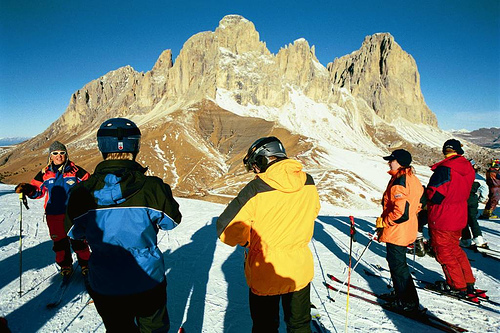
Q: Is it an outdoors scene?
A: Yes, it is outdoors.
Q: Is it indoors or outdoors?
A: It is outdoors.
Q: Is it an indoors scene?
A: No, it is outdoors.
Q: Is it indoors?
A: No, it is outdoors.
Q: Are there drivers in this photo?
A: No, there are no drivers.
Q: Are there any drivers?
A: No, there are no drivers.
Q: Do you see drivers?
A: No, there are no drivers.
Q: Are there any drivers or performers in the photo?
A: No, there are no drivers or performers.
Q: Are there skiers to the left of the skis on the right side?
A: Yes, there is a skier to the left of the skis.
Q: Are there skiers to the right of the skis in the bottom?
A: No, the skier is to the left of the skis.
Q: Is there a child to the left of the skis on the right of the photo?
A: No, there is a skier to the left of the skis.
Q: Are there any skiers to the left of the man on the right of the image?
A: Yes, there is a skier to the left of the man.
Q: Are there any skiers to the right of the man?
A: No, the skier is to the left of the man.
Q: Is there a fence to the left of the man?
A: No, there is a skier to the left of the man.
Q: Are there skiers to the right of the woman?
A: Yes, there is a skier to the right of the woman.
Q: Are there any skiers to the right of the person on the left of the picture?
A: Yes, there is a skier to the right of the woman.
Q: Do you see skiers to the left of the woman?
A: No, the skier is to the right of the woman.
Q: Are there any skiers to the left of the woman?
A: No, the skier is to the right of the woman.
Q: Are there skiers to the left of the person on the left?
A: No, the skier is to the right of the woman.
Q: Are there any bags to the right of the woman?
A: No, there is a skier to the right of the woman.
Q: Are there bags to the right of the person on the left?
A: No, there is a skier to the right of the woman.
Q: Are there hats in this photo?
A: Yes, there is a hat.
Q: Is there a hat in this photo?
A: Yes, there is a hat.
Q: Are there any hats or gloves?
A: Yes, there is a hat.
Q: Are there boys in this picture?
A: No, there are no boys.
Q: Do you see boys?
A: No, there are no boys.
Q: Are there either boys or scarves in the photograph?
A: No, there are no boys or scarves.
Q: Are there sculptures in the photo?
A: No, there are no sculptures.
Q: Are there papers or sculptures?
A: No, there are no sculptures or papers.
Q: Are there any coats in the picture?
A: Yes, there is a coat.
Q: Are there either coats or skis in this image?
A: Yes, there is a coat.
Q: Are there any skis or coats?
A: Yes, there is a coat.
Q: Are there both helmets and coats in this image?
A: Yes, there are both a coat and a helmet.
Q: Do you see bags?
A: No, there are no bags.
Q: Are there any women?
A: Yes, there is a woman.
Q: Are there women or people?
A: Yes, there is a woman.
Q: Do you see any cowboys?
A: No, there are no cowboys.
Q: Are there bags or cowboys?
A: No, there are no cowboys or bags.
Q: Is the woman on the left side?
A: Yes, the woman is on the left of the image.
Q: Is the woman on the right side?
A: No, the woman is on the left of the image.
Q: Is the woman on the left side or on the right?
A: The woman is on the left of the image.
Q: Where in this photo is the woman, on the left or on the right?
A: The woman is on the left of the image.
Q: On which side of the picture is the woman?
A: The woman is on the left of the image.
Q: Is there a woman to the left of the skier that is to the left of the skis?
A: Yes, there is a woman to the left of the skier.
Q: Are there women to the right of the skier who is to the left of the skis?
A: No, the woman is to the left of the skier.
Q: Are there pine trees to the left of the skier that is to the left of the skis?
A: No, there is a woman to the left of the skier.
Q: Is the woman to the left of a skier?
A: Yes, the woman is to the left of a skier.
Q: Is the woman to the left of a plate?
A: No, the woman is to the left of a skier.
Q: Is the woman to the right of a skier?
A: No, the woman is to the left of a skier.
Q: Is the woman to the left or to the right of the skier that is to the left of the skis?
A: The woman is to the left of the skier.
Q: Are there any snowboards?
A: No, there are no snowboards.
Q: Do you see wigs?
A: No, there are no wigs.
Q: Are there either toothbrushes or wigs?
A: No, there are no wigs or toothbrushes.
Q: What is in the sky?
A: The clouds are in the sky.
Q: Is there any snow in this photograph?
A: Yes, there is snow.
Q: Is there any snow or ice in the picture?
A: Yes, there is snow.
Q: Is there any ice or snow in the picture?
A: Yes, there is snow.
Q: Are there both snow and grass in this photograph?
A: No, there is snow but no grass.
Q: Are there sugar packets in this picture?
A: No, there are no sugar packets.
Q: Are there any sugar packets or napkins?
A: No, there are no sugar packets or napkins.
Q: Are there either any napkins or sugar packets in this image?
A: No, there are no sugar packets or napkins.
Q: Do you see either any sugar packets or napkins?
A: No, there are no sugar packets or napkins.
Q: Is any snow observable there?
A: Yes, there is snow.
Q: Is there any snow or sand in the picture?
A: Yes, there is snow.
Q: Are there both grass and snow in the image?
A: No, there is snow but no grass.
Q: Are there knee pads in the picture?
A: No, there are no knee pads.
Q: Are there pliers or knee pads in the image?
A: No, there are no knee pads or pliers.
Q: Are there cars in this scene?
A: No, there are no cars.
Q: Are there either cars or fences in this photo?
A: No, there are no cars or fences.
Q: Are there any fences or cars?
A: No, there are no cars or fences.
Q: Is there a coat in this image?
A: Yes, there is a coat.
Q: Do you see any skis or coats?
A: Yes, there is a coat.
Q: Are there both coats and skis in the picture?
A: Yes, there are both a coat and skis.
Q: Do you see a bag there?
A: No, there are no bags.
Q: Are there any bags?
A: No, there are no bags.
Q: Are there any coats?
A: Yes, there is a coat.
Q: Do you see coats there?
A: Yes, there is a coat.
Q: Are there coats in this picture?
A: Yes, there is a coat.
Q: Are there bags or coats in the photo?
A: Yes, there is a coat.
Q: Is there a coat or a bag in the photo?
A: Yes, there is a coat.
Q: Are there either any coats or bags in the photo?
A: Yes, there is a coat.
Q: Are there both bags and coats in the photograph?
A: No, there is a coat but no bags.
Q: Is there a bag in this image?
A: No, there are no bags.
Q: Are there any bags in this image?
A: No, there are no bags.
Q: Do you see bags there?
A: No, there are no bags.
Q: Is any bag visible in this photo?
A: No, there are no bags.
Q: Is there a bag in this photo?
A: No, there are no bags.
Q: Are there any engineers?
A: No, there are no engineers.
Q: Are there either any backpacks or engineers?
A: No, there are no engineers or backpacks.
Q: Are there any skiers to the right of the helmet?
A: Yes, there is a skier to the right of the helmet.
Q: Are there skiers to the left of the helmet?
A: No, the skier is to the right of the helmet.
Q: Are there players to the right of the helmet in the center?
A: No, there is a skier to the right of the helmet.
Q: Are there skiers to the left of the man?
A: Yes, there is a skier to the left of the man.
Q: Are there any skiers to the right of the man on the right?
A: No, the skier is to the left of the man.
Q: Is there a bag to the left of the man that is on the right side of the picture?
A: No, there is a skier to the left of the man.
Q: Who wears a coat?
A: The skier wears a coat.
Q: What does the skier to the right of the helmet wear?
A: The skier wears a coat.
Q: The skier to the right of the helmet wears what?
A: The skier wears a coat.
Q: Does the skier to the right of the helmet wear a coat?
A: Yes, the skier wears a coat.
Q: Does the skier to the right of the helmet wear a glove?
A: No, the skier wears a coat.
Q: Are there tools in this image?
A: No, there are no tools.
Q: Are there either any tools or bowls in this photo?
A: No, there are no tools or bowls.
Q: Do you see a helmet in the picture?
A: Yes, there is a helmet.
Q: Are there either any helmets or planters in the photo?
A: Yes, there is a helmet.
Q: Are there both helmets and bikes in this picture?
A: No, there is a helmet but no bikes.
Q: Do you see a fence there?
A: No, there are no fences.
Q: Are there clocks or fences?
A: No, there are no fences or clocks.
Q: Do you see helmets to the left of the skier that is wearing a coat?
A: Yes, there is a helmet to the left of the skier.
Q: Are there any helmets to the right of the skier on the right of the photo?
A: No, the helmet is to the left of the skier.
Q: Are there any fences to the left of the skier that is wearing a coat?
A: No, there is a helmet to the left of the skier.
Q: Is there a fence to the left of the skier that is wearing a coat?
A: No, there is a helmet to the left of the skier.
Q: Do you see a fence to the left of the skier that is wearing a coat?
A: No, there is a helmet to the left of the skier.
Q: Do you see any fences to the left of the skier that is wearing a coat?
A: No, there is a helmet to the left of the skier.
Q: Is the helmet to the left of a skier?
A: Yes, the helmet is to the left of a skier.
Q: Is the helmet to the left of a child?
A: No, the helmet is to the left of a skier.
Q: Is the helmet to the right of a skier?
A: No, the helmet is to the left of a skier.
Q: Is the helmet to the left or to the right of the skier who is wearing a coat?
A: The helmet is to the left of the skier.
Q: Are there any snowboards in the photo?
A: No, there are no snowboards.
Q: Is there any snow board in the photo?
A: No, there are no snowboards.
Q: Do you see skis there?
A: Yes, there are skis.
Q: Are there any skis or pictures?
A: Yes, there are skis.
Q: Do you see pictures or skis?
A: Yes, there are skis.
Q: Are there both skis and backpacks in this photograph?
A: No, there are skis but no backpacks.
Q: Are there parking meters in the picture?
A: No, there are no parking meters.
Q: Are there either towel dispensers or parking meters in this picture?
A: No, there are no parking meters or towel dispensers.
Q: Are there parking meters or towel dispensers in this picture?
A: No, there are no parking meters or towel dispensers.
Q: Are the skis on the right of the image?
A: Yes, the skis are on the right of the image.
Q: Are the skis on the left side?
A: No, the skis are on the right of the image.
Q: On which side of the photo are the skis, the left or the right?
A: The skis are on the right of the image.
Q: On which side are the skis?
A: The skis are on the right of the image.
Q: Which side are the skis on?
A: The skis are on the right of the image.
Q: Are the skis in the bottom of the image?
A: Yes, the skis are in the bottom of the image.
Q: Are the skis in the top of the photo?
A: No, the skis are in the bottom of the image.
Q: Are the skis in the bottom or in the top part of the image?
A: The skis are in the bottom of the image.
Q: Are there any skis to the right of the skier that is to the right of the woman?
A: Yes, there are skis to the right of the skier.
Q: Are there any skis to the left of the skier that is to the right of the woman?
A: No, the skis are to the right of the skier.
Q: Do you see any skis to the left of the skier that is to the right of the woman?
A: No, the skis are to the right of the skier.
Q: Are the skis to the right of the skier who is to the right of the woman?
A: Yes, the skis are to the right of the skier.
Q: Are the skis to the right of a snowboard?
A: No, the skis are to the right of the skier.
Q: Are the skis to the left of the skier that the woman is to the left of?
A: No, the skis are to the right of the skier.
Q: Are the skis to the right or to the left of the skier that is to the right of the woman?
A: The skis are to the right of the skier.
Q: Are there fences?
A: No, there are no fences.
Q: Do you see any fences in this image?
A: No, there are no fences.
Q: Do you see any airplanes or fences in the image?
A: No, there are no fences or airplanes.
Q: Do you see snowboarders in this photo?
A: No, there are no snowboarders.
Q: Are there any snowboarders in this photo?
A: No, there are no snowboarders.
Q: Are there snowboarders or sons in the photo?
A: No, there are no snowboarders or sons.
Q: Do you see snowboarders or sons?
A: No, there are no snowboarders or sons.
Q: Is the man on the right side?
A: Yes, the man is on the right of the image.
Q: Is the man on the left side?
A: No, the man is on the right of the image.